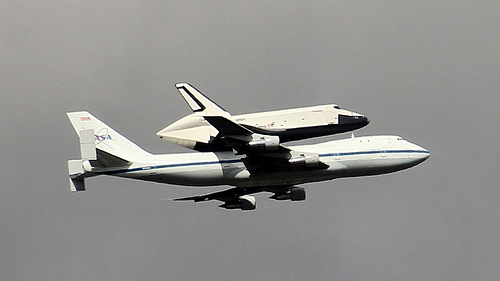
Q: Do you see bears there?
A: No, there are no bears.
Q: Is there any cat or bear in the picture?
A: No, there are no bears or cats.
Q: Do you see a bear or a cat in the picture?
A: No, there are no bears or cats.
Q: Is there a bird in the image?
A: No, there are no birds.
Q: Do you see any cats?
A: No, there are no cats.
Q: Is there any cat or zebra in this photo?
A: No, there are no cats or zebras.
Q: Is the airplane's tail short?
A: No, the tail is tall.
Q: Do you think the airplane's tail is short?
A: No, the tail is tall.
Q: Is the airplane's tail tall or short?
A: The tail is tall.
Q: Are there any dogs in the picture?
A: No, there are no dogs.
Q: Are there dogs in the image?
A: No, there are no dogs.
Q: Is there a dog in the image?
A: No, there are no dogs.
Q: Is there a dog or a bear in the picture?
A: No, there are no dogs or bears.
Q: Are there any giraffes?
A: No, there are no giraffes.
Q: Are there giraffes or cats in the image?
A: No, there are no giraffes or cats.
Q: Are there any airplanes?
A: Yes, there is an airplane.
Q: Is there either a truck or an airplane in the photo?
A: Yes, there is an airplane.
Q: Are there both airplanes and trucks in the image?
A: No, there is an airplane but no trucks.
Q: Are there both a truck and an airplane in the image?
A: No, there is an airplane but no trucks.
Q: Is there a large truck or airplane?
A: Yes, there is a large airplane.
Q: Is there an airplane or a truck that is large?
A: Yes, the airplane is large.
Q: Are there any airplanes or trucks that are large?
A: Yes, the airplane is large.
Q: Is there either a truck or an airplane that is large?
A: Yes, the airplane is large.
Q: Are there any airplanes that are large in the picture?
A: Yes, there is a large airplane.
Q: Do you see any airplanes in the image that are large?
A: Yes, there is an airplane that is large.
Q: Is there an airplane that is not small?
A: Yes, there is a large airplane.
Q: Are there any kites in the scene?
A: No, there are no kites.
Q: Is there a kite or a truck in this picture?
A: No, there are no kites or trucks.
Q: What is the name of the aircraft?
A: The aircraft is an airplane.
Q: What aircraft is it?
A: The aircraft is an airplane.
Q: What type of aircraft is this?
A: That is an airplane.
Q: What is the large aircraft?
A: The aircraft is an airplane.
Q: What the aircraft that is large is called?
A: The aircraft is an airplane.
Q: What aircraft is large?
A: The aircraft is an airplane.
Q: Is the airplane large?
A: Yes, the airplane is large.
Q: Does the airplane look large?
A: Yes, the airplane is large.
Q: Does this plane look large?
A: Yes, the plane is large.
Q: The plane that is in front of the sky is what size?
A: The airplane is large.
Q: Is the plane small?
A: No, the plane is large.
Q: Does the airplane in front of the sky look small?
A: No, the airplane is large.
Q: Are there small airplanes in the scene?
A: No, there is an airplane but it is large.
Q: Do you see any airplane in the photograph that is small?
A: No, there is an airplane but it is large.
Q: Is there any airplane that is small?
A: No, there is an airplane but it is large.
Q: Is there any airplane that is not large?
A: No, there is an airplane but it is large.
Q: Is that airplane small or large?
A: The airplane is large.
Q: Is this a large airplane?
A: Yes, this is a large airplane.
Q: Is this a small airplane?
A: No, this is a large airplane.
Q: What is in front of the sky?
A: The plane is in front of the sky.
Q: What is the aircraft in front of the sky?
A: The aircraft is an airplane.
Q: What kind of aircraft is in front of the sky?
A: The aircraft is an airplane.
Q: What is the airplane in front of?
A: The airplane is in front of the sky.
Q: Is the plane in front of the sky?
A: Yes, the plane is in front of the sky.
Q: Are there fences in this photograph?
A: No, there are no fences.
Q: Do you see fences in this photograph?
A: No, there are no fences.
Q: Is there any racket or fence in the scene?
A: No, there are no fences or rackets.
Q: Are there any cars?
A: No, there are no cars.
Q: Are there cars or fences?
A: No, there are no cars or fences.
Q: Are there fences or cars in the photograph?
A: No, there are no cars or fences.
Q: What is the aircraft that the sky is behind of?
A: The aircraft is an airplane.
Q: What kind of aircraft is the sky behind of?
A: The sky is behind the plane.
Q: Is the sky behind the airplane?
A: Yes, the sky is behind the airplane.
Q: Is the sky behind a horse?
A: No, the sky is behind the airplane.